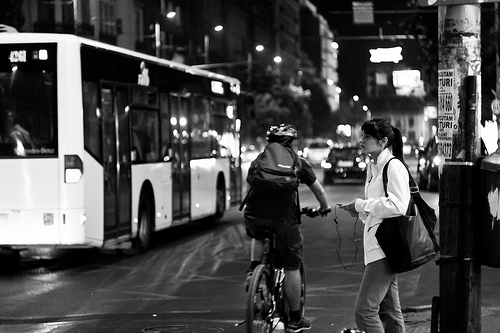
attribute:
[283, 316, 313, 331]
shoe — black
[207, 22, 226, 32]
light — glowing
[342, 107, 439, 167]
hair — Dark 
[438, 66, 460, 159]
poster — White 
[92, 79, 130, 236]
door — Back 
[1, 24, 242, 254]
bus — large, white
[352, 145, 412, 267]
shirt — white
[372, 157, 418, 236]
shoulder — girl's 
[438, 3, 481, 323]
pole — metal 